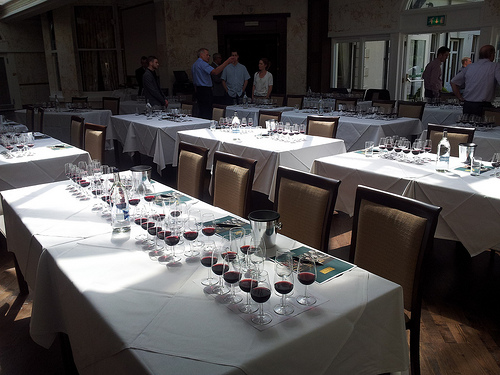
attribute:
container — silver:
[249, 207, 284, 247]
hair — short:
[433, 44, 451, 60]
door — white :
[404, 32, 430, 102]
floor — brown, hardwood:
[5, 144, 498, 373]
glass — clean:
[248, 269, 271, 328]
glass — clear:
[268, 261, 293, 317]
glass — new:
[293, 253, 318, 307]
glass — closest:
[238, 265, 259, 312]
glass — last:
[198, 238, 220, 285]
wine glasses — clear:
[103, 161, 140, 221]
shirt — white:
[250, 67, 277, 97]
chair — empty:
[166, 142, 211, 199]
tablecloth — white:
[21, 158, 423, 373]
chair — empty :
[206, 146, 256, 215]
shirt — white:
[252, 70, 279, 92]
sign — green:
[423, 9, 453, 30]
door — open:
[396, 20, 456, 121]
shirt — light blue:
[232, 58, 285, 105]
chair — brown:
[318, 170, 447, 362]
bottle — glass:
[434, 129, 455, 169]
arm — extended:
[211, 50, 237, 82]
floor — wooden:
[423, 275, 495, 370]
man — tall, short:
[221, 50, 251, 106]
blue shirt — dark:
[221, 62, 250, 96]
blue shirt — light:
[189, 56, 213, 88]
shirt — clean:
[258, 81, 271, 90]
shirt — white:
[255, 71, 272, 94]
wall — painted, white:
[404, 30, 478, 96]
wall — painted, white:
[162, 3, 304, 93]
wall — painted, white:
[329, 0, 406, 34]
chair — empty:
[343, 154, 450, 374]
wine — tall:
[408, 113, 468, 183]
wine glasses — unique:
[131, 197, 219, 267]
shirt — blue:
[192, 58, 214, 86]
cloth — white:
[2, 173, 422, 355]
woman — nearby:
[249, 69, 278, 110]